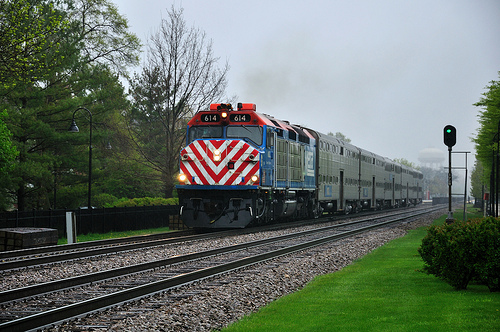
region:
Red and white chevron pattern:
[180, 139, 259, 183]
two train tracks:
[1, 226, 264, 286]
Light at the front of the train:
[220, 111, 227, 118]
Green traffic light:
[442, 123, 457, 147]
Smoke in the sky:
[240, 40, 457, 101]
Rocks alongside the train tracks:
[192, 265, 318, 289]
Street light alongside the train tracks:
[67, 105, 98, 214]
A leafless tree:
[145, 3, 238, 103]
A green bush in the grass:
[417, 215, 496, 293]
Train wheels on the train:
[312, 199, 338, 219]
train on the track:
[162, 95, 429, 216]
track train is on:
[33, 240, 190, 297]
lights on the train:
[177, 168, 267, 193]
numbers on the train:
[198, 110, 254, 126]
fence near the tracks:
[3, 205, 175, 226]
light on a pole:
[432, 115, 467, 207]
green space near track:
[353, 269, 448, 326]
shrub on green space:
[420, 207, 494, 299]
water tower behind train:
[415, 131, 446, 181]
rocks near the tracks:
[145, 299, 210, 316]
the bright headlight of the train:
[177, 173, 188, 183]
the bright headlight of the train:
[213, 149, 221, 161]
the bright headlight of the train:
[250, 173, 258, 183]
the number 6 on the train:
[200, 112, 210, 121]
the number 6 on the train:
[232, 114, 240, 124]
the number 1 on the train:
[207, 112, 213, 123]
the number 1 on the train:
[237, 112, 243, 122]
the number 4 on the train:
[212, 114, 216, 119]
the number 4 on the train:
[242, 113, 246, 121]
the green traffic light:
[446, 126, 453, 133]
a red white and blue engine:
[176, 101, 316, 227]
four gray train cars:
[309, 127, 424, 217]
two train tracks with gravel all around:
[1, 200, 440, 329]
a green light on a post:
[440, 121, 459, 218]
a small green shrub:
[417, 210, 499, 288]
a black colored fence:
[1, 203, 182, 239]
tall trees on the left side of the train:
[1, 0, 236, 210]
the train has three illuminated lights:
[171, 101, 262, 193]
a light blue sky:
[0, 2, 490, 174]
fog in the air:
[323, 105, 480, 200]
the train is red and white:
[147, 102, 319, 294]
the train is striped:
[169, 134, 449, 314]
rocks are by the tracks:
[168, 225, 279, 302]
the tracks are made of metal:
[66, 228, 155, 308]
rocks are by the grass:
[250, 253, 311, 304]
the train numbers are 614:
[182, 69, 353, 184]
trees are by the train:
[53, 115, 344, 273]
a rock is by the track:
[2, 208, 142, 329]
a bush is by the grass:
[388, 221, 450, 266]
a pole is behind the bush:
[419, 115, 489, 181]